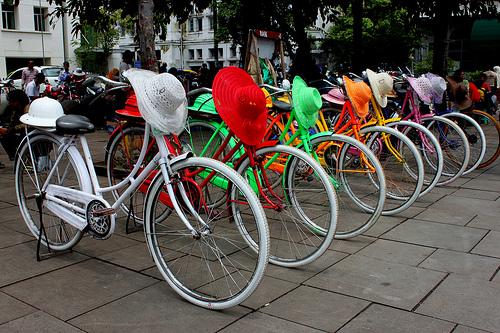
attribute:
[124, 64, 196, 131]
hat — white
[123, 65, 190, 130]
straw hat — white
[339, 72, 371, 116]
hat — orange, round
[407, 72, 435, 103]
pink hat — round, light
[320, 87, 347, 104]
pink hat — round, light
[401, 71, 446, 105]
hats — purple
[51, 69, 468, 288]
bicycles — colorful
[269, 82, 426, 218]
bike — orange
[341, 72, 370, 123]
hat — orange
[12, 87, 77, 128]
hat — white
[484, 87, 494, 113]
backpack — black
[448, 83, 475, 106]
shirt — brown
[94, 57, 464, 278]
bikes — colored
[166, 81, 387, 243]
bicycle — lime, green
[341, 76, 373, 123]
hat — color orange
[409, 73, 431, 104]
hat — purple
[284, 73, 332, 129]
hat — green, round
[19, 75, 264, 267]
bicycle — white framed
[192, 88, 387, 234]
bicycle — green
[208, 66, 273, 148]
hat — red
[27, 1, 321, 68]
buildings — white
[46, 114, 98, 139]
seat — black, bicycle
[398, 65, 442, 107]
hat — pink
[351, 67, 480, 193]
bike — pink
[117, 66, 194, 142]
hat — white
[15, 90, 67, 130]
hat — white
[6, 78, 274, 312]
bicycle — white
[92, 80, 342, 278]
bicycle — red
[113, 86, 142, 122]
hat — red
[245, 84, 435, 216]
bicycle — orange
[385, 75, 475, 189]
bicycle — purple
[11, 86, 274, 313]
bike — white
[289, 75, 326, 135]
hat — green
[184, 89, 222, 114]
hat — green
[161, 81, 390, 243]
bike — green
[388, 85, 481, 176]
bike — purple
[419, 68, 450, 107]
hat — purple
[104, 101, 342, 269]
bicycle — red